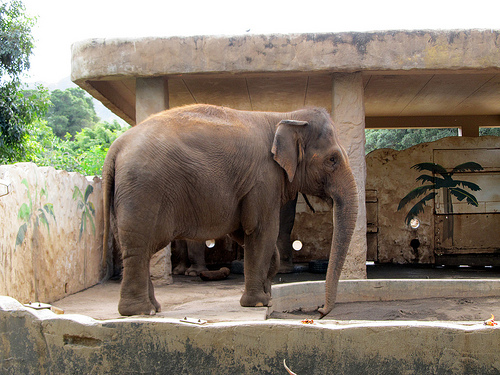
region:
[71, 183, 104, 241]
Painted palm tree on a wall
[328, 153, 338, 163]
Eye of an elephant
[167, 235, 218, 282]
Two elephant legs behind an elephant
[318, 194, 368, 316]
Elephant trunk on the ground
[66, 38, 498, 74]
Shelter ceiling above an elephant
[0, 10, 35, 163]
Tree behind an elelphant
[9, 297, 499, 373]
Stone wall in front of an elephant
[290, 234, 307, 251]
Hole in a wall behind an elephant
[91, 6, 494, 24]
White sky above a shelter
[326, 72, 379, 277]
Stone support post on a shelter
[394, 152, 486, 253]
palm tree painted on wall.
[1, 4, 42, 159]
Tall green tree outside enclosure.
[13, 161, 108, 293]
Elephant wall enclosure.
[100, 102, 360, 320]
Large gray elephant in enclosure.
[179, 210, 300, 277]
Four legs of another elephant.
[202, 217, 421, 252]
Round peek a boo holes in wall.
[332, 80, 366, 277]
Sandy colored column to enclosure structure.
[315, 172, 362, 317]
Long gray elephant trunk.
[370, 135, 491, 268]
Back wall to zoo enclosure.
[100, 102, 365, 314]
Elephant standing in place at zoo.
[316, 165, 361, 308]
the trunk of an elephant.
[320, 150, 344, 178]
the right eye of an elephant.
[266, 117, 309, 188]
the right ear of an elephant.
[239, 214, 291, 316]
the front right leg of an elephant.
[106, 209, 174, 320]
the right hind leg of an elephant.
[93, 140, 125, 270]
the tail of an elephant.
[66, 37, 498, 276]
a structure near an elephant.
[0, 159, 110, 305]
a stone wall near an elephant.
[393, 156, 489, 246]
a palm tree painting.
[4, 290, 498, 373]
a faded stone wall.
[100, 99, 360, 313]
A large brown elephant.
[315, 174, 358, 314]
Long trunk of a brown elephant.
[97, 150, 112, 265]
Long tail of an elephant.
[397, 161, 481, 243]
Palm tree painted on the wall in front of an elephant.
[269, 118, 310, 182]
The right side ear on an elephant.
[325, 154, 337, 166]
Eye on the right side of an elephant.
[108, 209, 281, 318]
Four legs on a brown colored elephant.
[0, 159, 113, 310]
Wall behind an elephant with palm trees on it.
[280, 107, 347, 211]
Large head of an elephant.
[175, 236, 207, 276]
Front legs of an elephant behind an elephant.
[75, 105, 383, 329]
elephant standing on concrete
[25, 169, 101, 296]
wall of zoo enclosure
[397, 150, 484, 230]
palm tree painted on wall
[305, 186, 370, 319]
hanging trunk of elephant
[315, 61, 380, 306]
post from roof to ground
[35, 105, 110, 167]
green leaves on trees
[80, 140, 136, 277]
tail on back of elephant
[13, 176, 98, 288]
two painted trees on wall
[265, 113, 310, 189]
ear on elephant head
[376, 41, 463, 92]
roof over zoo enclosure